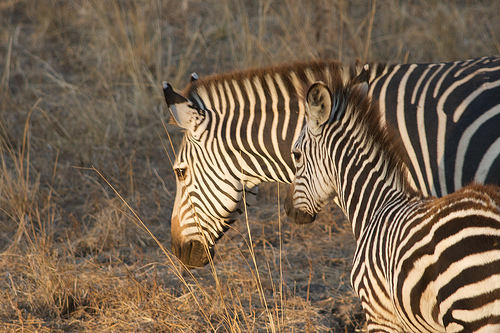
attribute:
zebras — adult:
[115, 33, 497, 326]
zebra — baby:
[239, 81, 499, 323]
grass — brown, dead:
[1, 76, 138, 323]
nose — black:
[176, 217, 223, 261]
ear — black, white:
[155, 78, 203, 133]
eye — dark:
[289, 146, 309, 170]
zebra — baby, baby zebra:
[285, 77, 497, 332]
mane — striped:
[330, 82, 407, 187]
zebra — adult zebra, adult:
[162, 57, 498, 272]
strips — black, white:
[407, 246, 479, 306]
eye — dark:
[170, 145, 219, 196]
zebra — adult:
[150, 52, 416, 328]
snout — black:
[169, 237, 188, 258]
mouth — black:
[177, 237, 213, 263]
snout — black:
[166, 237, 182, 257]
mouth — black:
[179, 237, 211, 267]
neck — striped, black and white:
[212, 73, 314, 197]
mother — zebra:
[157, 49, 498, 268]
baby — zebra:
[280, 75, 497, 330]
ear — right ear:
[346, 67, 375, 97]